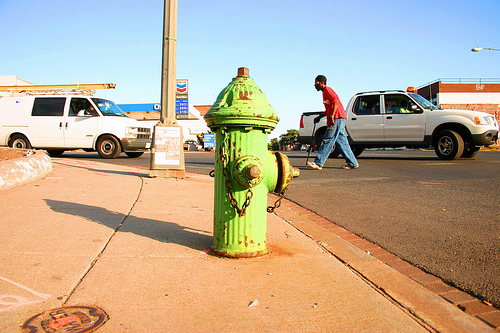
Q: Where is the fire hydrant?
A: On a sidewalk.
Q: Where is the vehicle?
A: On a street.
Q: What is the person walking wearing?
A: A red shirt.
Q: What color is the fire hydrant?
A: Green.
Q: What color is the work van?
A: White.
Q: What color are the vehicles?
A: White.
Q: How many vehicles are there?
A: Two.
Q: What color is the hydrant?
A: Green.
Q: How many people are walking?
A: One.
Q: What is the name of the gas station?
A: Chevron.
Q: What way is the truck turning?
A: Right.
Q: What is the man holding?
A: Cane.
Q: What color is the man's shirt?
A: Orange.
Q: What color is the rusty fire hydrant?
A: Green.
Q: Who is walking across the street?
A: A man.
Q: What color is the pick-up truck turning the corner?
A: White.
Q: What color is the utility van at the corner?
A: White.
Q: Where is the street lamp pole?
A: On the corner.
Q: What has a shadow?
A: The fire hydrant.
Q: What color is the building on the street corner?
A: Brown.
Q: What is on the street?
A: Cars.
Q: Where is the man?
A: On the street.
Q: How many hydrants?
A: 1.